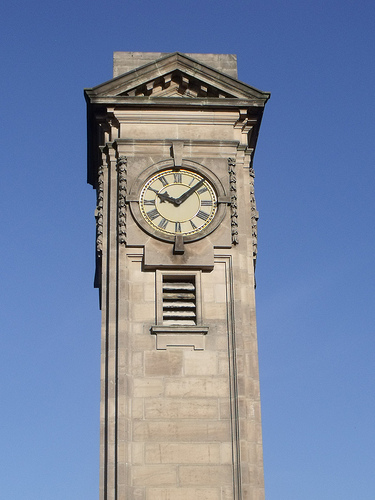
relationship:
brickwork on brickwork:
[95, 109, 266, 498] [82, 49, 271, 498]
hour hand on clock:
[155, 190, 176, 203] [81, 49, 271, 498]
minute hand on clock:
[174, 174, 205, 205] [137, 161, 222, 234]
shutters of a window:
[158, 272, 201, 323] [154, 267, 208, 329]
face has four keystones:
[137, 167, 220, 238] [122, 133, 238, 265]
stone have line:
[164, 378, 228, 397] [206, 417, 208, 441]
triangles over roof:
[109, 59, 242, 98] [76, 47, 272, 105]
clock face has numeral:
[138, 167, 219, 236] [171, 172, 187, 186]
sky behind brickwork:
[3, 0, 360, 498] [82, 49, 271, 498]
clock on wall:
[125, 155, 228, 244] [104, 118, 258, 496]